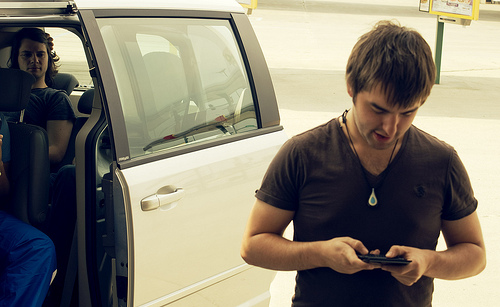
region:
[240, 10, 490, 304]
man pressing buttons on cell phone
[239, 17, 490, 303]
man standing next to open door of van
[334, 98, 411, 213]
necklace on neck of man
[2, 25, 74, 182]
person in back seat of van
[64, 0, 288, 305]
open sliding door of van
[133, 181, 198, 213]
handle on sliding door of van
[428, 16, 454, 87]
green sign support pole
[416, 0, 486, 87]
yellow framed sign on green pole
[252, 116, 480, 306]
brown short sleeve shirt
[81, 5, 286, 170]
black framed window on sliding door of van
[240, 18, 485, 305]
a man using an electronic device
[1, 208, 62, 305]
the knee and leg of a seated person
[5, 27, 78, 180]
a person with shoulder length hair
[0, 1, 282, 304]
a white van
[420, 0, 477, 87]
a yellow and green sign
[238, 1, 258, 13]
the bottom corner of a yellow sign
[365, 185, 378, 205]
a teardrop shaped pendant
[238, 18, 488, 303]
a man looking down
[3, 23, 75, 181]
a man sitting in shadow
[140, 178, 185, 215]
the door handle of a van door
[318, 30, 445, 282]
a man using a cell phone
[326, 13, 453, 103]
a man with brown hair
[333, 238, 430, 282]
a man holding a cell phone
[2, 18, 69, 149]
a young man sitting in a van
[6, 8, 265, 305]
a side door on a van opened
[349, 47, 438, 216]
a man wearing a necklace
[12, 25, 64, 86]
a young man with long hair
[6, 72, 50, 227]
a black seat in a van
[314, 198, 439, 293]
a young man texting on a phone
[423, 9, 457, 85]
a green post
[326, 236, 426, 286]
Two hands holding a cell phone.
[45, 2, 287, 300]
A car door is open.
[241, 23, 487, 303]
A man is using his cell phone.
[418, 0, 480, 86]
Yellow object on a green post.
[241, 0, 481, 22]
Two yellow objects near each other.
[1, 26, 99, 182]
A person is sitting in back of a car.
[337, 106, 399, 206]
A man is wearing a silver and blue necklace.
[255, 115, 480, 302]
A man is wearing a dark shirt.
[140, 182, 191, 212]
The handle is a pull type.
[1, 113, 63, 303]
Someone is sitting in the seat.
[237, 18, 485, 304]
a guy using his cellphone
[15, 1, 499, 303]
a guy standing next to the van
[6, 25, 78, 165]
a guy inside the van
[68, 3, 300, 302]
a door of the van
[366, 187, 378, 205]
a pendant the guy is wearing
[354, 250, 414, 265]
a cell phone the guy is using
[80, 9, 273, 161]
a window of the van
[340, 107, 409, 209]
a necklace the guy is wearing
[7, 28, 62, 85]
a guy has long hair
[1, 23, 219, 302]
a person in the van